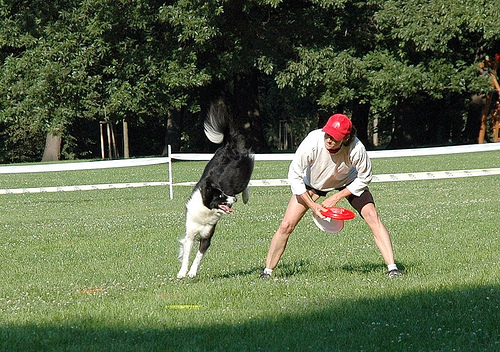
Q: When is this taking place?
A: Daytime.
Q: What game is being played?
A: Catch.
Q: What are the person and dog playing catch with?
A: Frisbee.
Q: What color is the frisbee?
A: Red.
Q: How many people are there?
A: One.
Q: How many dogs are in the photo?
A: One.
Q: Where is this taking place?
A: In a park.